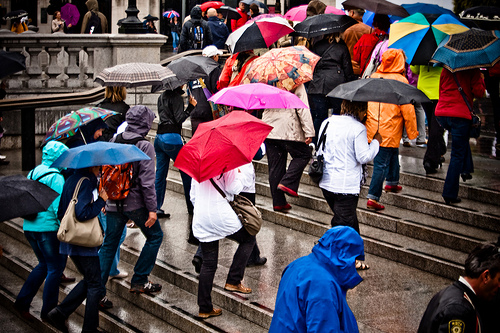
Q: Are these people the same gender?
A: Yes, all the people are female.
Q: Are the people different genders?
A: No, all the people are female.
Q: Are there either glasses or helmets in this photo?
A: No, there are no helmets or glasses.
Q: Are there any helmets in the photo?
A: No, there are no helmets.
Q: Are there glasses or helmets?
A: No, there are no helmets or glasses.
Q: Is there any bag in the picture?
A: Yes, there is a bag.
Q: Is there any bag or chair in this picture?
A: Yes, there is a bag.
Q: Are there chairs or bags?
A: Yes, there is a bag.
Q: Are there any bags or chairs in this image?
A: Yes, there is a bag.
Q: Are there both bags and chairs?
A: No, there is a bag but no chairs.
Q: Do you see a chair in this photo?
A: No, there are no chairs.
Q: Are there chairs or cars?
A: No, there are no chairs or cars.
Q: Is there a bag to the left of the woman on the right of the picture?
A: Yes, there is a bag to the left of the woman.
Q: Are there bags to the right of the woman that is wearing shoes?
A: No, the bag is to the left of the woman.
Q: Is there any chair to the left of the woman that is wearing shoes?
A: No, there is a bag to the left of the woman.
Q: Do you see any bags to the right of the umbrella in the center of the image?
A: Yes, there is a bag to the right of the umbrella.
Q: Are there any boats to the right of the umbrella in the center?
A: No, there is a bag to the right of the umbrella.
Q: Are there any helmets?
A: No, there are no helmets.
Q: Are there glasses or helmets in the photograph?
A: No, there are no helmets or glasses.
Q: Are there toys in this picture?
A: No, there are no toys.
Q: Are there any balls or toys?
A: No, there are no toys or balls.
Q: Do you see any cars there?
A: No, there are no cars.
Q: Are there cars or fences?
A: No, there are no cars or fences.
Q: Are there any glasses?
A: No, there are no glasses.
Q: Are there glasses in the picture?
A: No, there are no glasses.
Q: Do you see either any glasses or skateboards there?
A: No, there are no glasses or skateboards.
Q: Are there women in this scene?
A: Yes, there is a woman.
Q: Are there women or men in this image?
A: Yes, there is a woman.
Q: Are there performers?
A: No, there are no performers.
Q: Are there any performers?
A: No, there are no performers.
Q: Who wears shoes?
A: The woman wears shoes.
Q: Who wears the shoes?
A: The woman wears shoes.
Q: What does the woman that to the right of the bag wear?
A: The woman wears shoes.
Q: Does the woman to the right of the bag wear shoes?
A: Yes, the woman wears shoes.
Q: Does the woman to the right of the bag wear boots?
A: No, the woman wears shoes.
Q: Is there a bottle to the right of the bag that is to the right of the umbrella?
A: No, there is a woman to the right of the bag.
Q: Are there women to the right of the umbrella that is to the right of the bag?
A: Yes, there is a woman to the right of the umbrella.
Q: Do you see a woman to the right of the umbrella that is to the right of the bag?
A: Yes, there is a woman to the right of the umbrella.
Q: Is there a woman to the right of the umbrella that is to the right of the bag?
A: Yes, there is a woman to the right of the umbrella.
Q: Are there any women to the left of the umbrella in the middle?
A: No, the woman is to the right of the umbrella.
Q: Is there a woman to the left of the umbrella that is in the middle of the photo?
A: No, the woman is to the right of the umbrella.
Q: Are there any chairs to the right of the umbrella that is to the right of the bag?
A: No, there is a woman to the right of the umbrella.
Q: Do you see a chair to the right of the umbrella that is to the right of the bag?
A: No, there is a woman to the right of the umbrella.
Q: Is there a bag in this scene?
A: Yes, there is a bag.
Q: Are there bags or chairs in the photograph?
A: Yes, there is a bag.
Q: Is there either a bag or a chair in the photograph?
A: Yes, there is a bag.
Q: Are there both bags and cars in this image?
A: No, there is a bag but no cars.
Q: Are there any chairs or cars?
A: No, there are no cars or chairs.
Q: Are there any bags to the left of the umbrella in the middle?
A: Yes, there is a bag to the left of the umbrella.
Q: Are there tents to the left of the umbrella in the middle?
A: No, there is a bag to the left of the umbrella.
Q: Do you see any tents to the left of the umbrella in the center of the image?
A: No, there is a bag to the left of the umbrella.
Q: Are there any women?
A: Yes, there is a woman.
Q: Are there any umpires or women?
A: Yes, there is a woman.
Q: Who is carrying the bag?
A: The woman is carrying the bag.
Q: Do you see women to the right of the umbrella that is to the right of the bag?
A: Yes, there is a woman to the right of the umbrella.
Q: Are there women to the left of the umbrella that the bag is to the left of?
A: No, the woman is to the right of the umbrella.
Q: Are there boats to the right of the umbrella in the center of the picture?
A: No, there is a woman to the right of the umbrella.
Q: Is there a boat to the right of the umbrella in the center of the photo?
A: No, there is a woman to the right of the umbrella.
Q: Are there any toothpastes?
A: No, there are no toothpastes.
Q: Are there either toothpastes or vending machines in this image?
A: No, there are no toothpastes or vending machines.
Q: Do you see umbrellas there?
A: Yes, there is an umbrella.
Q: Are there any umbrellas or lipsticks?
A: Yes, there is an umbrella.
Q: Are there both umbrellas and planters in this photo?
A: No, there is an umbrella but no planters.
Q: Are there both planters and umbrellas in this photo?
A: No, there is an umbrella but no planters.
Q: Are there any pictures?
A: No, there are no pictures.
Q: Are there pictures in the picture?
A: No, there are no pictures.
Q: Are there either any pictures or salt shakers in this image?
A: No, there are no pictures or salt shakers.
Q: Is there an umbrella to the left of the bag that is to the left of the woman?
A: Yes, there is an umbrella to the left of the bag.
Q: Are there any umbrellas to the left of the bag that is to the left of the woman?
A: Yes, there is an umbrella to the left of the bag.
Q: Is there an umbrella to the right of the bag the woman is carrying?
A: No, the umbrella is to the left of the bag.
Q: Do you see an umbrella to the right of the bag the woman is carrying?
A: No, the umbrella is to the left of the bag.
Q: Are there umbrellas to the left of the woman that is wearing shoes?
A: Yes, there is an umbrella to the left of the woman.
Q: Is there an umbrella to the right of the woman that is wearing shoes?
A: No, the umbrella is to the left of the woman.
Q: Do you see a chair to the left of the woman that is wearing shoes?
A: No, there is an umbrella to the left of the woman.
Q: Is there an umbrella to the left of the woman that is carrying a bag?
A: Yes, there is an umbrella to the left of the woman.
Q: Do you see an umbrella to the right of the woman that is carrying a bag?
A: No, the umbrella is to the left of the woman.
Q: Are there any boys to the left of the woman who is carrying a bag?
A: No, there is an umbrella to the left of the woman.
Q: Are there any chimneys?
A: No, there are no chimneys.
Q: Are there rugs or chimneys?
A: No, there are no chimneys or rugs.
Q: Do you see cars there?
A: No, there are no cars.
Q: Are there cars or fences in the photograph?
A: No, there are no cars or fences.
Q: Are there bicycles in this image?
A: No, there are no bicycles.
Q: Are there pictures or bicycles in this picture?
A: No, there are no bicycles or pictures.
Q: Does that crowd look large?
A: Yes, the crowd is large.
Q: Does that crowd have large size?
A: Yes, the crowd is large.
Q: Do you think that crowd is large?
A: Yes, the crowd is large.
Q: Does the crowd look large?
A: Yes, the crowd is large.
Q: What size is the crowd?
A: The crowd is large.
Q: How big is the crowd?
A: The crowd is large.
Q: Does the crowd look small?
A: No, the crowd is large.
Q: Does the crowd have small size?
A: No, the crowd is large.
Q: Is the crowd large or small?
A: The crowd is large.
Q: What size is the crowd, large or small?
A: The crowd is large.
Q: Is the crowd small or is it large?
A: The crowd is large.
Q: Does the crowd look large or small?
A: The crowd is large.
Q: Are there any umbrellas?
A: Yes, there is an umbrella.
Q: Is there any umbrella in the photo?
A: Yes, there is an umbrella.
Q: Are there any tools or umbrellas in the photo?
A: Yes, there is an umbrella.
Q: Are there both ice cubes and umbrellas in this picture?
A: No, there is an umbrella but no ice cubes.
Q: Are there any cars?
A: No, there are no cars.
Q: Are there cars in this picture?
A: No, there are no cars.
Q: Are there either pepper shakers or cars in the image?
A: No, there are no cars or pepper shakers.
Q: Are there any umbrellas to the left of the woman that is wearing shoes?
A: Yes, there is an umbrella to the left of the woman.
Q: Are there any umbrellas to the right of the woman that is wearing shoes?
A: No, the umbrella is to the left of the woman.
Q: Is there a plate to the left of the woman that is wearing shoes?
A: No, there is an umbrella to the left of the woman.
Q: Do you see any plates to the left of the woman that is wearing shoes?
A: No, there is an umbrella to the left of the woman.